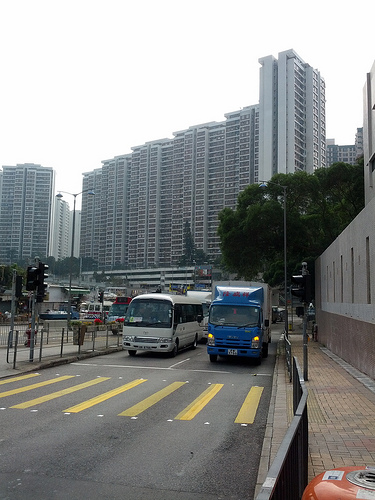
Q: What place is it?
A: It is a road.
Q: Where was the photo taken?
A: It was taken at the road.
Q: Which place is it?
A: It is a road.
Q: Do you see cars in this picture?
A: No, there are no cars.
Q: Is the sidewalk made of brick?
A: Yes, the sidewalk is made of brick.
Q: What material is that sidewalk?
A: The sidewalk is made of brick.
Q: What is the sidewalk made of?
A: The sidewalk is made of brick.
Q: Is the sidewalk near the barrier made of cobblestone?
A: No, the sidewalk is made of brick.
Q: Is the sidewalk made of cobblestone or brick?
A: The sidewalk is made of brick.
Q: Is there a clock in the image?
A: No, there are no clocks.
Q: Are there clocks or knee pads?
A: No, there are no clocks or knee pads.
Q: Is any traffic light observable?
A: Yes, there is a traffic light.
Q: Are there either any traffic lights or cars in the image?
A: Yes, there is a traffic light.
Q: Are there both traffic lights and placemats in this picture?
A: No, there is a traffic light but no placemats.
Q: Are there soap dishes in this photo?
A: No, there are no soap dishes.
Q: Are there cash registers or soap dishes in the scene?
A: No, there are no soap dishes or cash registers.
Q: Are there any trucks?
A: Yes, there is a truck.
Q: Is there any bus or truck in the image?
A: Yes, there is a truck.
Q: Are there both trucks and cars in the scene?
A: No, there is a truck but no cars.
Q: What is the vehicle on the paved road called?
A: The vehicle is a truck.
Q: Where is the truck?
A: The truck is on the road.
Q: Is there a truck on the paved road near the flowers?
A: Yes, there is a truck on the road.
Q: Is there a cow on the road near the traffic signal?
A: No, there is a truck on the road.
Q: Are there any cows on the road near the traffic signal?
A: No, there is a truck on the road.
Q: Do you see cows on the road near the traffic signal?
A: No, there is a truck on the road.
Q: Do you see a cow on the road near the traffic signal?
A: No, there is a truck on the road.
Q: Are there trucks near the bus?
A: Yes, there is a truck near the bus.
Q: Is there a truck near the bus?
A: Yes, there is a truck near the bus.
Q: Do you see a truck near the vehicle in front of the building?
A: Yes, there is a truck near the bus.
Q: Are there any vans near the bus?
A: No, there is a truck near the bus.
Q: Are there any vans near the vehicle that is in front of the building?
A: No, there is a truck near the bus.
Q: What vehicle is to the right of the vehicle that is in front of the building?
A: The vehicle is a truck.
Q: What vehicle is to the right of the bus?
A: The vehicle is a truck.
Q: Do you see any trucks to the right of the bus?
A: Yes, there is a truck to the right of the bus.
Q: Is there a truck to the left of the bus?
A: No, the truck is to the right of the bus.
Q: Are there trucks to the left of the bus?
A: No, the truck is to the right of the bus.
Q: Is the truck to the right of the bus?
A: Yes, the truck is to the right of the bus.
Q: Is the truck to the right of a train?
A: No, the truck is to the right of the bus.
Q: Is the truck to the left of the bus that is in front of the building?
A: No, the truck is to the right of the bus.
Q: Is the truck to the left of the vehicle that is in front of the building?
A: No, the truck is to the right of the bus.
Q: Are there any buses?
A: Yes, there is a bus.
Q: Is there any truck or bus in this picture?
A: Yes, there is a bus.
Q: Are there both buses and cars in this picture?
A: No, there is a bus but no cars.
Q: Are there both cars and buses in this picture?
A: No, there is a bus but no cars.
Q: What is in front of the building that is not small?
A: The bus is in front of the building.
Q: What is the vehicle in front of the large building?
A: The vehicle is a bus.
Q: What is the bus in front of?
A: The bus is in front of the building.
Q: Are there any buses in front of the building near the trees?
A: Yes, there is a bus in front of the building.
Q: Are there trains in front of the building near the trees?
A: No, there is a bus in front of the building.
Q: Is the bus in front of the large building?
A: Yes, the bus is in front of the building.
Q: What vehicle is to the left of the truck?
A: The vehicle is a bus.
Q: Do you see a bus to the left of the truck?
A: Yes, there is a bus to the left of the truck.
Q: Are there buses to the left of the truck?
A: Yes, there is a bus to the left of the truck.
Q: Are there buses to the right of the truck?
A: No, the bus is to the left of the truck.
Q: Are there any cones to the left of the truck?
A: No, there is a bus to the left of the truck.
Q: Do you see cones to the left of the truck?
A: No, there is a bus to the left of the truck.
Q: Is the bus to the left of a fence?
A: No, the bus is to the left of a truck.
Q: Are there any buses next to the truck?
A: Yes, there is a bus next to the truck.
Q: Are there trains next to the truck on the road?
A: No, there is a bus next to the truck.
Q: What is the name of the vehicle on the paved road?
A: The vehicle is a bus.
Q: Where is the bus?
A: The bus is on the road.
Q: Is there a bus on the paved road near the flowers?
A: Yes, there is a bus on the road.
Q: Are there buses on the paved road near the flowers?
A: Yes, there is a bus on the road.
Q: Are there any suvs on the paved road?
A: No, there is a bus on the road.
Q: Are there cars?
A: No, there are no cars.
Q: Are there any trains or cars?
A: No, there are no cars or trains.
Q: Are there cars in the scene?
A: No, there are no cars.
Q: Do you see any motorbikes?
A: No, there are no motorbikes.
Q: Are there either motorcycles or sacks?
A: No, there are no motorcycles or sacks.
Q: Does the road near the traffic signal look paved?
A: Yes, the road is paved.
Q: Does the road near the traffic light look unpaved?
A: No, the road is paved.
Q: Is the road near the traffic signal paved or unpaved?
A: The road is paved.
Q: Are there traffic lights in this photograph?
A: Yes, there is a traffic light.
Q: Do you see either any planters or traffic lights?
A: Yes, there is a traffic light.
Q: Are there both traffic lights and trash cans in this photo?
A: No, there is a traffic light but no trash cans.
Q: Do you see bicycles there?
A: No, there are no bicycles.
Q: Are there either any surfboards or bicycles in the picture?
A: No, there are no bicycles or surfboards.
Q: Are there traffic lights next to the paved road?
A: Yes, there is a traffic light next to the road.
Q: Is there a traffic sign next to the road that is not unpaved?
A: No, there is a traffic light next to the road.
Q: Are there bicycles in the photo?
A: No, there are no bicycles.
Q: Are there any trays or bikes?
A: No, there are no bikes or trays.